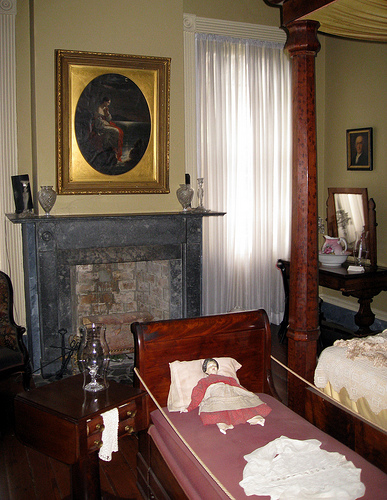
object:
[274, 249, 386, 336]
table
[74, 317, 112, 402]
vase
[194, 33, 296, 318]
curtains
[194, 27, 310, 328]
window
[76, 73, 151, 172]
painting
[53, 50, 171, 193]
mat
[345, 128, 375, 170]
painting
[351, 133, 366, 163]
president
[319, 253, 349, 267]
basin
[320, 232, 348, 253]
pitcher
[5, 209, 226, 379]
fireplace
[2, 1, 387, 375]
wall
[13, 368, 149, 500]
dresser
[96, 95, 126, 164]
doll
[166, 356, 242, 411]
pillow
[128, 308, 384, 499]
bed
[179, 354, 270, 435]
china doll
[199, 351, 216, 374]
black hair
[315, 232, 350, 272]
vase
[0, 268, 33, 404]
chair